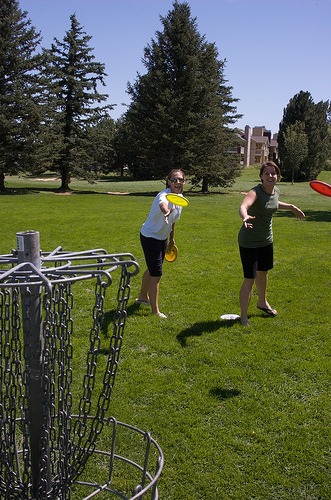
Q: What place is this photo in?
A: It is at the field.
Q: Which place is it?
A: It is a field.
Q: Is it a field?
A: Yes, it is a field.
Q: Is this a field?
A: Yes, it is a field.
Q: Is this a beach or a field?
A: It is a field.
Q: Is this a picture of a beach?
A: No, the picture is showing a field.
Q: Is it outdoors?
A: Yes, it is outdoors.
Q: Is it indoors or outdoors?
A: It is outdoors.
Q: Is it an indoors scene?
A: No, it is outdoors.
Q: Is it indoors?
A: No, it is outdoors.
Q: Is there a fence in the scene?
A: No, there are no fences.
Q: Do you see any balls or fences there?
A: No, there are no fences or balls.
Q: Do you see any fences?
A: No, there are no fences.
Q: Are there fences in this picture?
A: No, there are no fences.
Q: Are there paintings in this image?
A: No, there are no paintings.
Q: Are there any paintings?
A: No, there are no paintings.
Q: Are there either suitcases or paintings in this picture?
A: No, there are no paintings or suitcases.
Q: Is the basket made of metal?
A: Yes, the basket is made of metal.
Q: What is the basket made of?
A: The basket is made of metal.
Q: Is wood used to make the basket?
A: No, the basket is made of metal.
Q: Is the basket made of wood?
A: No, the basket is made of metal.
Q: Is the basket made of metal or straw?
A: The basket is made of metal.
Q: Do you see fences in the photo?
A: No, there are no fences.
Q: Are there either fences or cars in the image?
A: No, there are no fences or cars.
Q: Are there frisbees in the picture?
A: Yes, there is a frisbee.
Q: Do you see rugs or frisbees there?
A: Yes, there is a frisbee.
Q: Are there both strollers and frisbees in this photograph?
A: No, there is a frisbee but no strollers.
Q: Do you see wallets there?
A: No, there are no wallets.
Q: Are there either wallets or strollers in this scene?
A: No, there are no wallets or strollers.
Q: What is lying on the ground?
A: The frisbee is lying on the ground.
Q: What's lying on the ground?
A: The frisbee is lying on the ground.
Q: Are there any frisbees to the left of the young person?
A: Yes, there is a frisbee to the left of the person.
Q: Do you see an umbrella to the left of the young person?
A: No, there is a frisbee to the left of the person.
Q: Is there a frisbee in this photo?
A: Yes, there is a frisbee.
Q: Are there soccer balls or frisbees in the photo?
A: Yes, there is a frisbee.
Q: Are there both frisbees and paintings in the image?
A: No, there is a frisbee but no paintings.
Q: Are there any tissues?
A: No, there are no tissues.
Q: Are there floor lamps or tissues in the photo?
A: No, there are no tissues or floor lamps.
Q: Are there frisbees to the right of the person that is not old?
A: Yes, there is a frisbee to the right of the person.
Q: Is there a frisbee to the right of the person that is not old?
A: Yes, there is a frisbee to the right of the person.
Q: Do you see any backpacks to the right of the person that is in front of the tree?
A: No, there is a frisbee to the right of the person.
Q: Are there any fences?
A: No, there are no fences.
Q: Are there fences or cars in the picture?
A: No, there are no fences or cars.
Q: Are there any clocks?
A: No, there are no clocks.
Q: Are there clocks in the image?
A: No, there are no clocks.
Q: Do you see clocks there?
A: No, there are no clocks.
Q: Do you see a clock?
A: No, there are no clocks.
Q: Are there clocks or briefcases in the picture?
A: No, there are no clocks or briefcases.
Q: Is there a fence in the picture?
A: No, there are no fences.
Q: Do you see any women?
A: Yes, there is a woman.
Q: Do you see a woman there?
A: Yes, there is a woman.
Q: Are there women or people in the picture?
A: Yes, there is a woman.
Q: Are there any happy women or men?
A: Yes, there is a happy woman.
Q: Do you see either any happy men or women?
A: Yes, there is a happy woman.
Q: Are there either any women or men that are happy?
A: Yes, the woman is happy.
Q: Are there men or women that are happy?
A: Yes, the woman is happy.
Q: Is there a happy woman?
A: Yes, there is a happy woman.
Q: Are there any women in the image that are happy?
A: Yes, there is a woman that is happy.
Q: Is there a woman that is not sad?
A: Yes, there is a happy woman.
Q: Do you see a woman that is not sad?
A: Yes, there is a happy woman.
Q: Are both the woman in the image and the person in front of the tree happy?
A: Yes, both the woman and the person are happy.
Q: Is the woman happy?
A: Yes, the woman is happy.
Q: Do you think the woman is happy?
A: Yes, the woman is happy.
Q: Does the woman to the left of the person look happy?
A: Yes, the woman is happy.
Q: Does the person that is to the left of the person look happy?
A: Yes, the woman is happy.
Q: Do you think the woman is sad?
A: No, the woman is happy.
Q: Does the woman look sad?
A: No, the woman is happy.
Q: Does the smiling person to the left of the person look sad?
A: No, the woman is happy.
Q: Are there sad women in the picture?
A: No, there is a woman but she is happy.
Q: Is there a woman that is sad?
A: No, there is a woman but she is happy.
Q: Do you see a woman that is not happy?
A: No, there is a woman but she is happy.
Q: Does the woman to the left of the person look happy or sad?
A: The woman is happy.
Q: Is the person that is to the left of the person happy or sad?
A: The woman is happy.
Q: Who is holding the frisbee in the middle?
A: The woman is holding the frisbee.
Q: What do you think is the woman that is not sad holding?
A: The woman is holding the frisbee.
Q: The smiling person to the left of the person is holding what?
A: The woman is holding the frisbee.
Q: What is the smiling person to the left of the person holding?
A: The woman is holding the frisbee.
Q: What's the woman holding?
A: The woman is holding the frisbee.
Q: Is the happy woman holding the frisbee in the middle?
A: Yes, the woman is holding the frisbee.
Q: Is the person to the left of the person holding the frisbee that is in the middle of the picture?
A: Yes, the woman is holding the frisbee.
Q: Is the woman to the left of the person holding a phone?
A: No, the woman is holding the frisbee.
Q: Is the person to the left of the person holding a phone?
A: No, the woman is holding the frisbee.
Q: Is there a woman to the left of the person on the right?
A: Yes, there is a woman to the left of the person.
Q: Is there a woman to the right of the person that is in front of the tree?
A: No, the woman is to the left of the person.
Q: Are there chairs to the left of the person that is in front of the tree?
A: No, there is a woman to the left of the person.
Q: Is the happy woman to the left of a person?
A: Yes, the woman is to the left of a person.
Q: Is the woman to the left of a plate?
A: No, the woman is to the left of a person.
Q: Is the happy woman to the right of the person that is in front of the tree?
A: No, the woman is to the left of the person.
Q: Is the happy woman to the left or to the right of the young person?
A: The woman is to the left of the person.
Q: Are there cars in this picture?
A: No, there are no cars.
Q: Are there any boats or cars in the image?
A: No, there are no cars or boats.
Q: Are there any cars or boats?
A: No, there are no cars or boats.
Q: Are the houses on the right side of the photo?
A: Yes, the houses are on the right of the image.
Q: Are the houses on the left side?
A: No, the houses are on the right of the image.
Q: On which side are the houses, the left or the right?
A: The houses are on the right of the image.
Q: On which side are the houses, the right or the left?
A: The houses are on the right of the image.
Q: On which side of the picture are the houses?
A: The houses are on the right of the image.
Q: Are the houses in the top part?
A: Yes, the houses are in the top of the image.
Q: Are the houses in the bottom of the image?
A: No, the houses are in the top of the image.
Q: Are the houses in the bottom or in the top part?
A: The houses are in the top of the image.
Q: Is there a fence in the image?
A: No, there are no fences.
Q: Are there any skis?
A: No, there are no skis.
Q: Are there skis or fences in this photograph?
A: No, there are no skis or fences.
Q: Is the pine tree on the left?
A: Yes, the pine tree is on the left of the image.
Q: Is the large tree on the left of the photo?
A: Yes, the pine tree is on the left of the image.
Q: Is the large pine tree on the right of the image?
A: No, the pine tree is on the left of the image.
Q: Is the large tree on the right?
A: No, the pine tree is on the left of the image.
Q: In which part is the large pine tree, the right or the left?
A: The pine tree is on the left of the image.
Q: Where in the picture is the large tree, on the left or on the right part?
A: The pine tree is on the left of the image.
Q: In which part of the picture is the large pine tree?
A: The pine is on the left of the image.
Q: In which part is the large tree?
A: The pine is on the left of the image.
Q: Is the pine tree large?
A: Yes, the pine tree is large.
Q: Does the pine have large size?
A: Yes, the pine is large.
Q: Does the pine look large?
A: Yes, the pine is large.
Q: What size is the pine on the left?
A: The pine tree is large.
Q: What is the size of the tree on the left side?
A: The pine tree is large.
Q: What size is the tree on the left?
A: The pine tree is large.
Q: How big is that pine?
A: The pine is large.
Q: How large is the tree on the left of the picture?
A: The pine is large.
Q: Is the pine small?
A: No, the pine is large.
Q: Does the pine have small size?
A: No, the pine is large.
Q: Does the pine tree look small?
A: No, the pine tree is large.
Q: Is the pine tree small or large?
A: The pine tree is large.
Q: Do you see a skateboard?
A: No, there are no skateboards.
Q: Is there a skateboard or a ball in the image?
A: No, there are no skateboards or balls.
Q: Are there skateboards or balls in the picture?
A: No, there are no skateboards or balls.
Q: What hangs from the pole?
A: The chain hangs from the pole.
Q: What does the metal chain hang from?
A: The chain hangs from the pole.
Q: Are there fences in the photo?
A: No, there are no fences.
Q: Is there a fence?
A: No, there are no fences.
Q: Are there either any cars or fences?
A: No, there are no fences or cars.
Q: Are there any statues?
A: No, there are no statues.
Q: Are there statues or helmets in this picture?
A: No, there are no statues or helmets.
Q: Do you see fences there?
A: No, there are no fences.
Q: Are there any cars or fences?
A: No, there are no fences or cars.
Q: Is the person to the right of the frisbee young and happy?
A: Yes, the person is young and happy.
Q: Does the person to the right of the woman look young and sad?
A: No, the person is young but happy.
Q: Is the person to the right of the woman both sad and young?
A: No, the person is young but happy.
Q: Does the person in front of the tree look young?
A: Yes, the person is young.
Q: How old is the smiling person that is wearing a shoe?
A: The person is young.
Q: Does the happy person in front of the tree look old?
A: No, the person is young.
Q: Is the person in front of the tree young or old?
A: The person is young.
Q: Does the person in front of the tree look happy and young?
A: Yes, the person is happy and young.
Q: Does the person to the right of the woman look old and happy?
A: No, the person is happy but young.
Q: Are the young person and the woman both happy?
A: Yes, both the person and the woman are happy.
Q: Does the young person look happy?
A: Yes, the person is happy.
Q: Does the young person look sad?
A: No, the person is happy.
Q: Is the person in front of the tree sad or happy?
A: The person is happy.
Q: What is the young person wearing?
A: The person is wearing a shoe.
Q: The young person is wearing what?
A: The person is wearing a shoe.